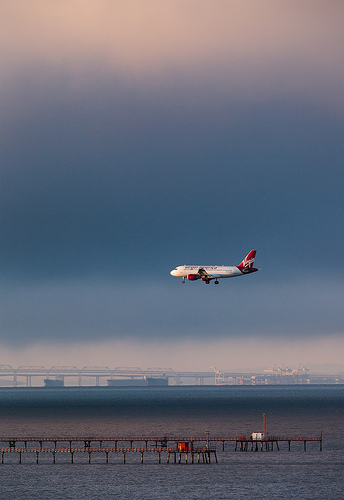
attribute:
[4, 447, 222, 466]
dock — wooden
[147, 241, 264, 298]
jet — virgin airlines, passenger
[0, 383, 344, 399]
wall — large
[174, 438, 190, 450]
box — red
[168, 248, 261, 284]
jet — jumbo, passenger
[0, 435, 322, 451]
dock — small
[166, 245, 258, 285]
plane — red and white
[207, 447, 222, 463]
post — wooden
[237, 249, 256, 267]
wing — red and white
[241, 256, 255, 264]
stripe — white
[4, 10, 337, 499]
weather — dark blue, cloudy